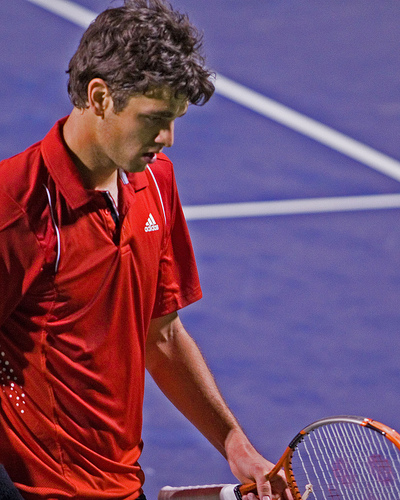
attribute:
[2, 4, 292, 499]
tennis player — male, concentrating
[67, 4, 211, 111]
hair — curly, brown, dark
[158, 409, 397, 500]
tennis racket — orange, black, silver, red, white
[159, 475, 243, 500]
handle — white taped, orange, white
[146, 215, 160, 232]
logo — adidas, white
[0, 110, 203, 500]
shirt — red, adidas, short sleeved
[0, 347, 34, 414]
design — white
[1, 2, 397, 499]
tennis court — blue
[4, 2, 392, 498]
turf — purple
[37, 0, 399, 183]
line — white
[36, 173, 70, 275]
stripe — white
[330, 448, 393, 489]
design — red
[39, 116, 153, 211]
collar — red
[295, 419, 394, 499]
strings — mesh